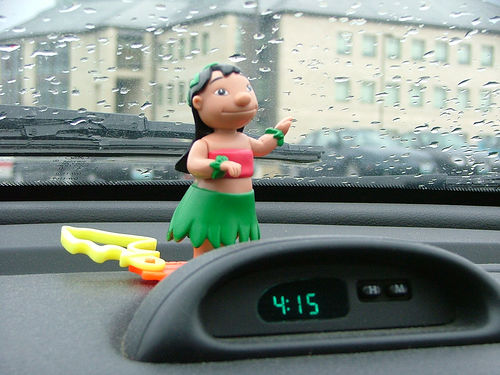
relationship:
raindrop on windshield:
[458, 73, 473, 86] [0, 0, 498, 192]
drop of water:
[225, 52, 248, 62] [48, 31, 182, 83]